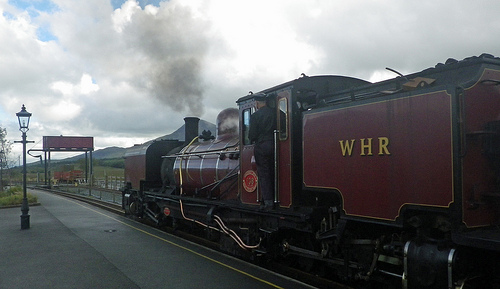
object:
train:
[119, 51, 497, 288]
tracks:
[20, 177, 122, 213]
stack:
[182, 116, 200, 144]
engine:
[159, 137, 239, 198]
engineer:
[247, 94, 274, 206]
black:
[246, 105, 282, 201]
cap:
[250, 92, 271, 104]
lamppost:
[11, 132, 34, 230]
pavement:
[0, 207, 146, 287]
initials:
[338, 134, 390, 159]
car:
[299, 52, 499, 247]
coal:
[443, 58, 458, 66]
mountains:
[0, 119, 215, 174]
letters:
[338, 139, 356, 157]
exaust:
[119, 1, 221, 144]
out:
[182, 111, 199, 120]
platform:
[0, 184, 355, 289]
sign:
[41, 135, 96, 152]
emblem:
[239, 170, 260, 196]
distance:
[0, 135, 128, 169]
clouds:
[0, 0, 499, 163]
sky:
[0, 0, 499, 170]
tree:
[0, 126, 15, 193]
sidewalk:
[18, 189, 357, 288]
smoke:
[124, 1, 219, 116]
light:
[14, 105, 30, 136]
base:
[20, 213, 31, 230]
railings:
[75, 190, 121, 202]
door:
[236, 102, 291, 205]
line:
[19, 186, 278, 288]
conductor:
[245, 95, 285, 213]